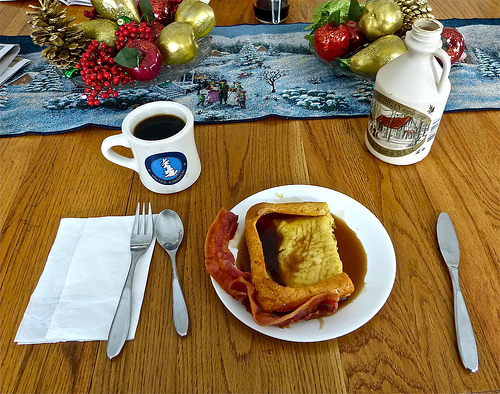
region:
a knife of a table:
[437, 210, 487, 376]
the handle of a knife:
[454, 290, 484, 373]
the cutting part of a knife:
[431, 208, 468, 267]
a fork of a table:
[124, 198, 150, 347]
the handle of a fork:
[111, 281, 135, 357]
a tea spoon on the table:
[155, 209, 195, 339]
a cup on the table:
[118, 104, 200, 194]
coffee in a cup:
[140, 117, 177, 139]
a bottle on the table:
[381, 38, 443, 161]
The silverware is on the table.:
[103, 202, 195, 362]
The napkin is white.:
[9, 194, 169, 356]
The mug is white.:
[84, 93, 207, 200]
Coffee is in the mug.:
[115, 101, 197, 151]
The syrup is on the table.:
[348, 14, 478, 180]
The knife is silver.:
[409, 195, 493, 377]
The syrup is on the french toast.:
[190, 156, 415, 341]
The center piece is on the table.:
[33, 5, 221, 96]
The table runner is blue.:
[5, 24, 497, 143]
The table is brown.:
[7, 13, 493, 393]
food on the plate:
[187, 199, 395, 356]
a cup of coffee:
[90, 103, 215, 228]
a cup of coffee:
[99, 80, 208, 174]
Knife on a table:
[425, 205, 485, 376]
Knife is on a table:
[427, 205, 484, 370]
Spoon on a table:
[150, 201, 190, 338]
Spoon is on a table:
[150, 200, 191, 340]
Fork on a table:
[103, 197, 153, 359]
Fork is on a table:
[104, 197, 156, 359]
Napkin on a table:
[10, 204, 165, 350]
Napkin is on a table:
[10, 207, 161, 347]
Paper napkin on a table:
[11, 210, 164, 347]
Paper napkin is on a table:
[8, 210, 161, 343]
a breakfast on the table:
[27, 15, 476, 321]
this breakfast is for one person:
[74, 53, 481, 365]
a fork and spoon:
[104, 179, 198, 359]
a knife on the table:
[417, 207, 492, 379]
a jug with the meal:
[343, 6, 470, 171]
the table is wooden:
[213, 126, 349, 181]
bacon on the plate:
[209, 202, 261, 329]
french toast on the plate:
[276, 213, 337, 295]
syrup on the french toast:
[229, 199, 369, 314]